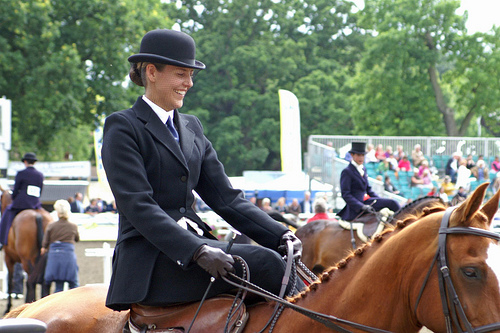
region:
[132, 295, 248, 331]
a brown horse saddle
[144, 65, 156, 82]
an ear of a woman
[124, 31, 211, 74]
a small black hat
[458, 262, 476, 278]
an eye of a horse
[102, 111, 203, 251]
an arm of a woman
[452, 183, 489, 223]
an ear of a horse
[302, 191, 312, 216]
a male spectator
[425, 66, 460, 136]
a branch of a tree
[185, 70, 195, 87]
the nose of a woman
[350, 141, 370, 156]
a black top hat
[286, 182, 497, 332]
The horses mane is braided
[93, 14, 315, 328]
The rider is sitting sidesaddle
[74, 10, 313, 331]
The rider is wearing a bowler hat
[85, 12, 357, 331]
The rider is wearing a suit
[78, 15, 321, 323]
The rider is wearing gloves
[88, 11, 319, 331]
The rider is smiling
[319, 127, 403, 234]
The man is wearing a top hat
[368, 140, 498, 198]
Spectators are in the stands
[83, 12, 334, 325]
The rider is holder a crop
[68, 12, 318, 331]
The rider is wearing a tie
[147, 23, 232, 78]
hat on a lady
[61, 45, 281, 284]
lady on a horse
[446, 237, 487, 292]
eye of the horse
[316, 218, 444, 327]
brown neck of horse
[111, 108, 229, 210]
black and white suit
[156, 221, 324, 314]
gloves on woman's hands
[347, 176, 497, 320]
brown and white horse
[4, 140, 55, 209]
person in background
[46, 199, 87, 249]
woman in the background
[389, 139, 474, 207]
people watching in the audience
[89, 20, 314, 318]
woman riding a horse.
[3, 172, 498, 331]
the horse is brown.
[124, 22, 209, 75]
woman wearing a hat.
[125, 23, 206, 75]
woman's hat is black.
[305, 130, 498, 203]
people sitting in the stands.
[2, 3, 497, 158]
the trees are green.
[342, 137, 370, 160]
man wearing a top hat.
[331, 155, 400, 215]
man's outfit is black.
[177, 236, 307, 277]
woman is wearing gloves.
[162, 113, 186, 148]
woman's tie is blue.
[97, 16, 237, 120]
the woman is smiling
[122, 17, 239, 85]
woman wearing a hat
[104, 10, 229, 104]
the hat is black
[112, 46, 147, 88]
woman's hair in a bun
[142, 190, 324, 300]
woman's gloves are black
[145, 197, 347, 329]
woman holding streins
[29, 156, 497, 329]
the horse is brown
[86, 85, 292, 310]
woman's outfit is black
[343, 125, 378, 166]
man wearing a tophat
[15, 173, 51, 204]
white label on man's back